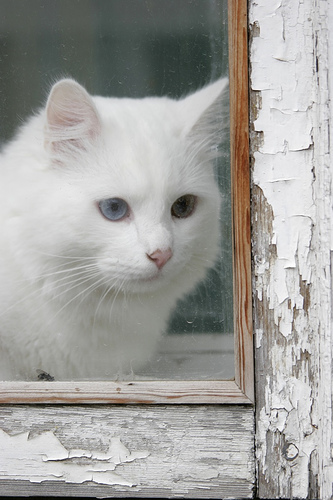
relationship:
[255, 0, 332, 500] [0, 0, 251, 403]
paint peeling on window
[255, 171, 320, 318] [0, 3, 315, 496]
paint peeling on window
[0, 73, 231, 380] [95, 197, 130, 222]
cat has eye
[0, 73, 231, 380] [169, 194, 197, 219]
cat has eye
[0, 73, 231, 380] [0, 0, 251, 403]
cat looking through window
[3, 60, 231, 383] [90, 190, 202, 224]
cat has eyes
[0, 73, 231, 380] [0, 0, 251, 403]
cat in front of window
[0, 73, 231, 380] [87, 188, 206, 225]
cat has eyes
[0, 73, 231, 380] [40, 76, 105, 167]
cat has ear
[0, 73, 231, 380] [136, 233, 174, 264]
cat has nose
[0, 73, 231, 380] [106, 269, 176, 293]
cat has mouth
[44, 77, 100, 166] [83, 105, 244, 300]
cat's ear on head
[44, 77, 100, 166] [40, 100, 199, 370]
cat's ear on cat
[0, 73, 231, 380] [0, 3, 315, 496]
cat inside window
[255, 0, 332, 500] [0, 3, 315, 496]
paint chipping on window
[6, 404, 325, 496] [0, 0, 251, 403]
paint chipping on window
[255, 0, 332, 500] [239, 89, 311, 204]
paint chipping on frame